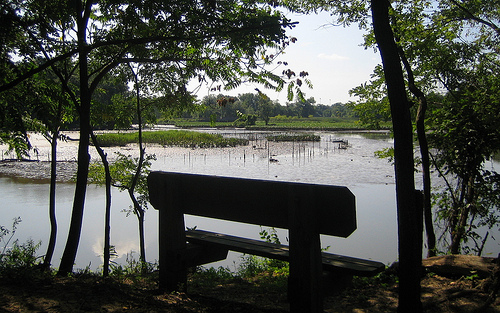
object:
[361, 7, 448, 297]
tree trunk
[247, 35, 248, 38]
leaves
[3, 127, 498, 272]
water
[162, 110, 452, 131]
grass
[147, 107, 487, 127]
shoreline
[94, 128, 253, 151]
island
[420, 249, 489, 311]
light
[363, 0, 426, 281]
trees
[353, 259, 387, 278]
edge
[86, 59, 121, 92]
branches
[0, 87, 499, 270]
pond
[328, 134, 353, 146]
log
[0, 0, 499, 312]
park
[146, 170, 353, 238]
wood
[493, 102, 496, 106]
green leaves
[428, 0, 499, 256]
tree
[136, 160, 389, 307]
bench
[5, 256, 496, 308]
ground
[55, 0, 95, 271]
tree